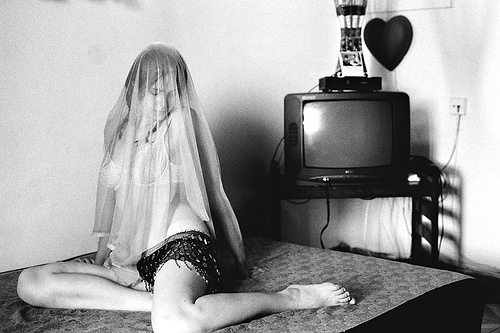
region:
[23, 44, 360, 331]
woman on a mattress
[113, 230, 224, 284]
bottom attire on woman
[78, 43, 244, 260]
lucid cover over woman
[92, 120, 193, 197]
under garment on woman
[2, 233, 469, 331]
mattress woman sits on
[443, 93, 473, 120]
outlet for electrical cords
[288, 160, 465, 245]
stand by the wall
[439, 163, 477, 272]
shadow from the stand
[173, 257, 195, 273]
jewels hanging off woman's bottom attire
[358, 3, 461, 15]
image on the wall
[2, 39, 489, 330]
A woman sitting on a bed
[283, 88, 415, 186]
The television screen is turned off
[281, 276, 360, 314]
A foot is bare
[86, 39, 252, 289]
Woman is wearing a veil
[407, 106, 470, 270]
Shadows on the wall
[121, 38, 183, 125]
The woman has her eyes closed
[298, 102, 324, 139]
Light glare on the TV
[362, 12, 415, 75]
A heart design on the wall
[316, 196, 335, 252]
A black electrical cord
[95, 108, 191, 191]
Woman's bra is white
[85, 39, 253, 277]
A veil over a woman's head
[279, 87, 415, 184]
A television set is not on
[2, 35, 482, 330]
Woman sitting on the bed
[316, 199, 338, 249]
A black electric cord hooked to the TV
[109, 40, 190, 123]
Woman is looking downwards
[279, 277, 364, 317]
The foot is bare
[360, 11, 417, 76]
A heart object on the wall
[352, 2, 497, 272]
Shadows are on the wall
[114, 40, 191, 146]
The woman has dark hair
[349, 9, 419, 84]
heart on the wall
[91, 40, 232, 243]
veil on the girl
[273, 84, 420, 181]
tv on the stand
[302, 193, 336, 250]
cord on the tv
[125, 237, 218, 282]
shorts on the girl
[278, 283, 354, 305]
foot of the girl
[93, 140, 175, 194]
bra on the girl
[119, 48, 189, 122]
head of the girl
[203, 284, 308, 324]
leg of the girl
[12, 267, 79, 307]
knee of the girl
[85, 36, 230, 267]
Woman wearing a veil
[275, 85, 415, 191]
An older TV set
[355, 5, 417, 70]
3-D Heart hanging on wall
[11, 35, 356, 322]
Woman wearing veil sitting on bed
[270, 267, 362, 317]
Foot of a woman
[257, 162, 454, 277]
A black TV stand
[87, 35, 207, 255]
Dark haired woman wearing veil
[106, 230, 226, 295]
Woman wearing crocheted black shorts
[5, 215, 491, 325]
Mattress of bed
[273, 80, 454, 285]
Television on TV stand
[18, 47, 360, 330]
A woman with a veil is sitting on the bed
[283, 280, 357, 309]
Foot of a woman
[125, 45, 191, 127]
Head of a woman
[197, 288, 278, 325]
Leg of a woman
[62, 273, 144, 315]
Leg of a woman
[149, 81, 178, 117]
Face of a woman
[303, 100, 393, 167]
Screen of a television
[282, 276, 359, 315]
Foot of a woman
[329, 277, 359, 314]
Toes on a foot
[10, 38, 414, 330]
a woman posing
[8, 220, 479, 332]
a person on bed